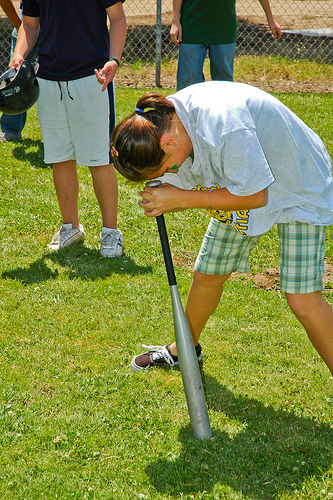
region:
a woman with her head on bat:
[84, 90, 323, 331]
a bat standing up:
[116, 265, 304, 468]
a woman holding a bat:
[122, 170, 258, 325]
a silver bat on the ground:
[139, 209, 300, 497]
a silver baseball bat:
[115, 238, 267, 482]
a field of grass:
[19, 274, 297, 492]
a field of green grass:
[50, 291, 312, 498]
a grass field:
[65, 343, 265, 495]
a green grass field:
[57, 320, 325, 496]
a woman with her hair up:
[107, 69, 328, 256]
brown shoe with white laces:
[128, 340, 202, 369]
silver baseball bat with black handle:
[146, 180, 211, 437]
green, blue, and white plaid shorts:
[194, 212, 324, 293]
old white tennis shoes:
[43, 223, 123, 258]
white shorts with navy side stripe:
[37, 72, 114, 165]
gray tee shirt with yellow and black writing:
[148, 81, 331, 236]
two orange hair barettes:
[109, 146, 118, 156]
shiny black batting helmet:
[1, 60, 39, 115]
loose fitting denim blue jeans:
[176, 43, 232, 90]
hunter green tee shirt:
[179, 0, 237, 45]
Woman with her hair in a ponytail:
[111, 94, 210, 181]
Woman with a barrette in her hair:
[105, 123, 191, 183]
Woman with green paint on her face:
[129, 141, 194, 177]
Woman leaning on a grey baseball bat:
[136, 160, 215, 441]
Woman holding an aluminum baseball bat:
[138, 181, 211, 441]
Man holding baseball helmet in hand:
[0, 58, 42, 119]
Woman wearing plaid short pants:
[192, 210, 325, 296]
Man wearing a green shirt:
[173, 0, 243, 47]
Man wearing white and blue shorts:
[35, 62, 116, 172]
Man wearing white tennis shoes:
[45, 219, 126, 258]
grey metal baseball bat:
[146, 182, 214, 439]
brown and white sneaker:
[130, 343, 204, 372]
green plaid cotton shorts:
[190, 217, 326, 293]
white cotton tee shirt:
[169, 81, 332, 237]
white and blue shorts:
[31, 73, 116, 168]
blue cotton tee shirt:
[19, 0, 124, 81]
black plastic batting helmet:
[1, 58, 39, 113]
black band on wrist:
[109, 56, 120, 67]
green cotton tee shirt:
[180, 0, 238, 45]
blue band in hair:
[134, 105, 145, 114]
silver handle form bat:
[132, 177, 160, 193]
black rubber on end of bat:
[145, 217, 196, 291]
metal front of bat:
[166, 304, 218, 451]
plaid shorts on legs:
[195, 217, 323, 300]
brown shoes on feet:
[112, 346, 168, 374]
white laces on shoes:
[146, 338, 175, 365]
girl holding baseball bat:
[128, 91, 307, 449]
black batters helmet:
[0, 57, 46, 119]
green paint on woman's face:
[172, 158, 180, 170]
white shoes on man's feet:
[51, 228, 127, 270]